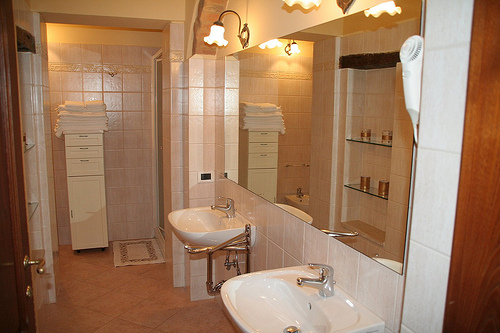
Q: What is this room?
A: A bathroom.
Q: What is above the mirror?
A: Lamps.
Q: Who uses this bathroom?
A: Hotel guests.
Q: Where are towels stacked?
A: On a cabinet.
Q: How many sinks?
A: 2.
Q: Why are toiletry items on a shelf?
A: For the use of guest.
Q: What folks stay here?
A: Travelers and salesmen.